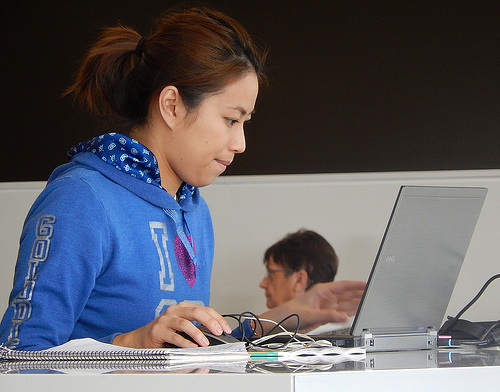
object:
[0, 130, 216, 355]
shirt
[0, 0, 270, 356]
girl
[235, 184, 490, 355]
laptop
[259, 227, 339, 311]
person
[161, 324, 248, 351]
mouse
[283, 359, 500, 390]
table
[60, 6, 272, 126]
hair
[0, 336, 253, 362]
notebook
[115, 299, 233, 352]
hand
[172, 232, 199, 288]
heart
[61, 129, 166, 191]
liner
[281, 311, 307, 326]
cables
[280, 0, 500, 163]
wall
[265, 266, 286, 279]
glasses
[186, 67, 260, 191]
face